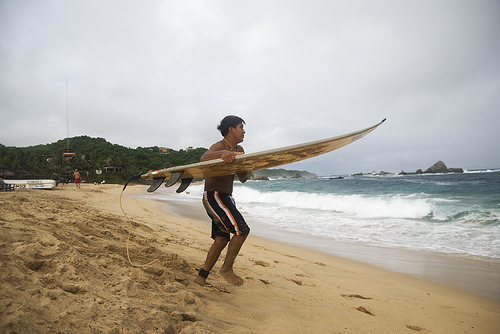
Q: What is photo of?
A: Man holding surfboard.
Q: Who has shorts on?
A: The man.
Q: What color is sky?
A: Gray.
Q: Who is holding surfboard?
A: Man on beach.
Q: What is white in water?
A: Waves crashing.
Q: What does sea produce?
A: Waves.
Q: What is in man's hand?
A: Surfboard.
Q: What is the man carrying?
A: Surfboard.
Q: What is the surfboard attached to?
A: The man's foot.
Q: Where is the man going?
A: To the ocean.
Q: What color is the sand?
A: Tan.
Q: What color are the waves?
A: White.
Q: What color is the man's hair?
A: Black.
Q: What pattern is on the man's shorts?
A: Stripes.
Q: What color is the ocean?
A: Blue.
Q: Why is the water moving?
A: There is a wave.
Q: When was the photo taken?
A: Daytime.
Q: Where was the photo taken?
A: In a beach.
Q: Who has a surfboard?
A: A man.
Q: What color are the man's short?
A: Black with white stripes.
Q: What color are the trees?
A: Green.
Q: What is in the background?
A: Trees.